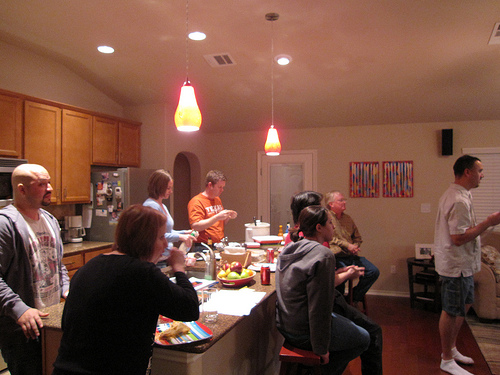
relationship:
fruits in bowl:
[218, 261, 245, 275] [214, 272, 255, 292]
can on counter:
[258, 265, 275, 295] [204, 245, 288, 336]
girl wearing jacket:
[287, 200, 351, 270] [273, 234, 338, 356]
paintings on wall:
[340, 153, 422, 209] [322, 131, 422, 243]